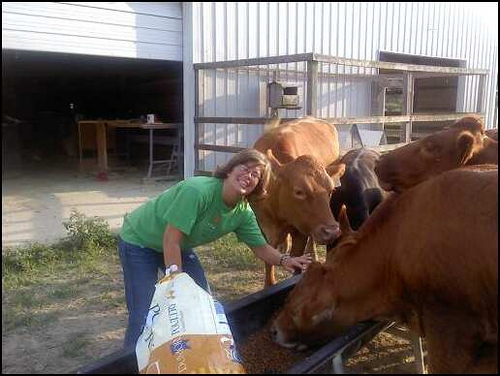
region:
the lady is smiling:
[230, 172, 254, 196]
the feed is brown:
[245, 342, 277, 369]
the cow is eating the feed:
[266, 301, 319, 353]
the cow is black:
[351, 156, 371, 193]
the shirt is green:
[171, 191, 210, 226]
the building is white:
[209, 11, 261, 42]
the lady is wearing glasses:
[234, 153, 270, 194]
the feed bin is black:
[238, 301, 272, 323]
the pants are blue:
[125, 258, 146, 293]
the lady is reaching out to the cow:
[267, 242, 341, 300]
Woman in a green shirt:
[109, 143, 276, 283]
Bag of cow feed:
[119, 257, 251, 372]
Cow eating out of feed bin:
[269, 237, 403, 358]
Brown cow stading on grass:
[265, 145, 351, 251]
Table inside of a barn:
[68, 106, 187, 182]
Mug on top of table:
[137, 106, 161, 130]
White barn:
[4, 2, 197, 178]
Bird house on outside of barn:
[259, 66, 311, 118]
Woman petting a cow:
[112, 144, 273, 289]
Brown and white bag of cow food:
[127, 266, 267, 374]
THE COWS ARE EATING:
[242, 106, 499, 374]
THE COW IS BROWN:
[235, 100, 343, 286]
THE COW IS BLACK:
[313, 130, 399, 265]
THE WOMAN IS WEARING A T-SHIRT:
[103, 168, 283, 270]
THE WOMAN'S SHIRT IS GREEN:
[107, 159, 275, 263]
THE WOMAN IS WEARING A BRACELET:
[276, 247, 293, 274]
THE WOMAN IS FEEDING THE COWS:
[111, 140, 321, 362]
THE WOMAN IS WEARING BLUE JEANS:
[111, 224, 225, 349]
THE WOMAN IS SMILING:
[231, 169, 253, 191]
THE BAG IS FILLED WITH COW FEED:
[115, 258, 250, 375]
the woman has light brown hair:
[217, 148, 271, 195]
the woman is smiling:
[218, 160, 270, 196]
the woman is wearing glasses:
[236, 161, 265, 179]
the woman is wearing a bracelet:
[278, 250, 288, 263]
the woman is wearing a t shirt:
[121, 170, 268, 260]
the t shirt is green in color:
[118, 173, 267, 260]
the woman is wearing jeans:
[111, 228, 212, 348]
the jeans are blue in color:
[119, 233, 215, 358]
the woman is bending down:
[109, 150, 276, 358]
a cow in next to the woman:
[236, 115, 339, 296]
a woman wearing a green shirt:
[127, 151, 295, 258]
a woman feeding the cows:
[106, 135, 408, 355]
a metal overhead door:
[15, 5, 196, 71]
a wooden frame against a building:
[194, 47, 434, 178]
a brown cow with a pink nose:
[249, 113, 351, 239]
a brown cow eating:
[272, 235, 357, 375]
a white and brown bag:
[126, 284, 250, 374]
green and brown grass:
[20, 265, 107, 334]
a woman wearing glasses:
[220, 150, 272, 200]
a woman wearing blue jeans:
[100, 223, 227, 338]